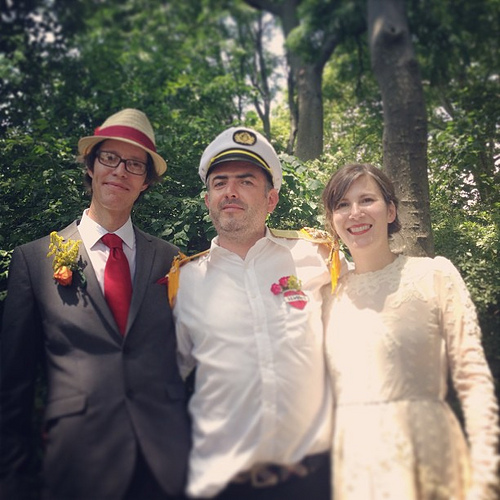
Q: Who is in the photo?
A: Three people.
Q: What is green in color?
A: The trees.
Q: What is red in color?
A: The tie.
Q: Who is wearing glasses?
A: Man on left.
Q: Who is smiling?
A: The man.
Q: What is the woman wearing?
A: A dress.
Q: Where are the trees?
A: Behind the people.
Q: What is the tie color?
A: Red.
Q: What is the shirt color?
A: White.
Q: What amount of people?
A: Three.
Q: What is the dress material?
A: Lace.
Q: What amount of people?
A: Three.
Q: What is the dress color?
A: White.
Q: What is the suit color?
A: Grey.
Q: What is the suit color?
A: Grey.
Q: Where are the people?
A: Outside somewhere.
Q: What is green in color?
A: The trees.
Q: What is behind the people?
A: Trees.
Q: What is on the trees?
A: Leaves.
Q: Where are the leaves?
A: On the tree.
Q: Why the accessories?
A: Costume party.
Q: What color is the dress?
A: Peach.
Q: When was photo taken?
A: Daytime.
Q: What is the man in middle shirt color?
A: White.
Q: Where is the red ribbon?
A: On hat.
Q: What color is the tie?
A: Red.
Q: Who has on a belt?
A: The middle man.